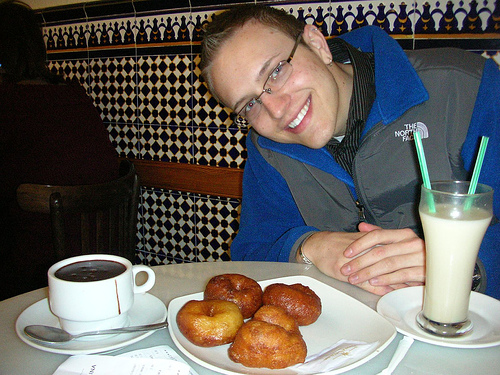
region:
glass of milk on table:
[380, 105, 499, 344]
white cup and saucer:
[11, 247, 176, 374]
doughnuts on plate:
[172, 252, 327, 373]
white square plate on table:
[153, 243, 423, 373]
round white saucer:
[358, 277, 498, 354]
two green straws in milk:
[392, 117, 499, 220]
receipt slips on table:
[47, 333, 215, 373]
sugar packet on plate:
[277, 308, 381, 373]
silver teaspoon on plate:
[16, 314, 188, 356]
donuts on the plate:
[160, 242, 355, 371]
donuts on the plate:
[178, 265, 314, 365]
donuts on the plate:
[179, 267, 327, 372]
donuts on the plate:
[183, 261, 336, 373]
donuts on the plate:
[175, 265, 329, 373]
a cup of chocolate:
[40, 247, 153, 352]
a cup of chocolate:
[39, 241, 149, 339]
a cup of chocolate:
[36, 245, 153, 344]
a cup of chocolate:
[51, 247, 151, 355]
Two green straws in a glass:
[407, 122, 492, 338]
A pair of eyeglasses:
[227, 22, 307, 127]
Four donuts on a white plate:
[160, 270, 395, 370]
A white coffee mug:
[41, 250, 157, 340]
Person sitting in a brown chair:
[0, 0, 140, 290]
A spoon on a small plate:
[10, 285, 170, 350]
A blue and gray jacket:
[225, 20, 495, 300]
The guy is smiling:
[185, 0, 345, 150]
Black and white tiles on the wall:
[40, 50, 240, 265]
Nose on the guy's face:
[255, 87, 291, 122]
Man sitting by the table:
[200, 1, 499, 297]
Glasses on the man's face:
[230, 32, 304, 127]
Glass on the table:
[416, 180, 492, 335]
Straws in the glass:
[411, 129, 490, 214]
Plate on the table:
[165, 274, 397, 373]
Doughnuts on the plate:
[175, 273, 322, 370]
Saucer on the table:
[13, 292, 167, 355]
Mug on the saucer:
[46, 253, 154, 339]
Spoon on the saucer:
[22, 321, 167, 342]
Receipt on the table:
[51, 344, 201, 374]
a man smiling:
[162, 15, 352, 142]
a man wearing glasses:
[185, 17, 356, 175]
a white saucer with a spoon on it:
[13, 247, 186, 369]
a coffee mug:
[19, 257, 157, 374]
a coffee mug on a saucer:
[13, 250, 163, 371]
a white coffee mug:
[22, 237, 170, 339]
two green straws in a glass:
[399, 121, 499, 224]